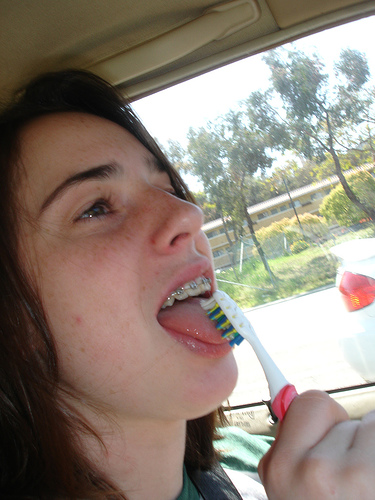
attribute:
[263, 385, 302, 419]
grip — pink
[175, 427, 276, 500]
shirt — green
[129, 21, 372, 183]
sky — bright, clear